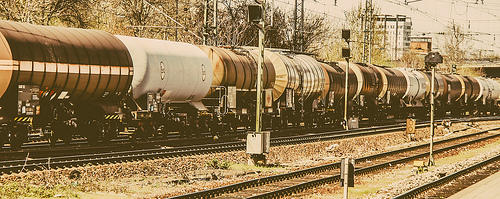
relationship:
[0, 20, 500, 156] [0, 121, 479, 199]
car on grass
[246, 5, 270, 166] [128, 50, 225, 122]
light poles in front of tank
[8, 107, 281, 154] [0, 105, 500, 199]
wheels are touching tracks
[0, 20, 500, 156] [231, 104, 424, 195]
car on tracks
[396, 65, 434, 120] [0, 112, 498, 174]
car on track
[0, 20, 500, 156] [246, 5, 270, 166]
car next to light poles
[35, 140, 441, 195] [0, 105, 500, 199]
grass next to tracks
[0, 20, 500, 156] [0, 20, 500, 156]
car carrying a car